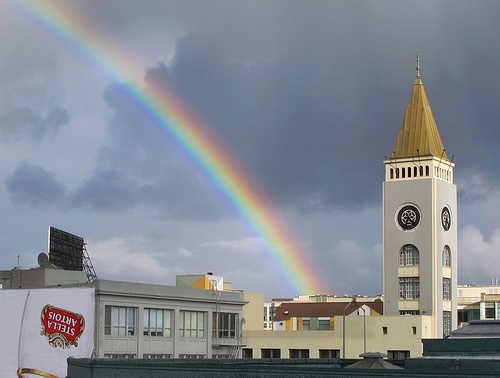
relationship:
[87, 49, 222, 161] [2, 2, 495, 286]
rainbow in sky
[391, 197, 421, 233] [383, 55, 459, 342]
clock on church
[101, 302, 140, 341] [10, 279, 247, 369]
windows on building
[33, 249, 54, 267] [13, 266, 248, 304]
satellite on roof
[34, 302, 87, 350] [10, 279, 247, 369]
logo on building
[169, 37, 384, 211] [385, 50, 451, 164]
clouds above roof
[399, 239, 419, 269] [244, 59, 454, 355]
window of church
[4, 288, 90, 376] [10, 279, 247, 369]
ad on building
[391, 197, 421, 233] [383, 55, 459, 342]
clock in church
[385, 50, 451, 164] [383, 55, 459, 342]
steeple on church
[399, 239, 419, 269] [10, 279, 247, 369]
window in building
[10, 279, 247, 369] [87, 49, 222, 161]
building and rainbow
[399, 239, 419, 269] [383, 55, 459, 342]
window on church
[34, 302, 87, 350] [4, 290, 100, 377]
logo on wall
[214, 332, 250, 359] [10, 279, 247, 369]
escape on building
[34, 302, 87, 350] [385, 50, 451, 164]
billboard on roof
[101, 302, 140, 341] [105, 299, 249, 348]
windows in row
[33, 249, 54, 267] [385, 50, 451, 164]
satellite on roof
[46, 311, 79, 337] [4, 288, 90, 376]
stella artois on billboard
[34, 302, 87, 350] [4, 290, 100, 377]
art on wall